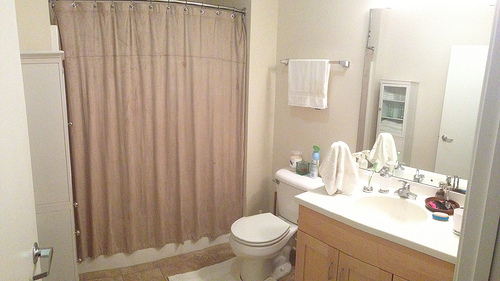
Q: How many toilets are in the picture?
A: One.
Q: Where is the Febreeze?
A: On the toilet.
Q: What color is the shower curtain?
A: Brown.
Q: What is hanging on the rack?
A: A towel.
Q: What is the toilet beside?
A: The shower.